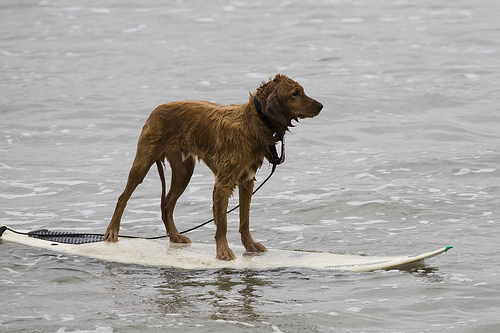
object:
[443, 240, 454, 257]
tip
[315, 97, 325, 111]
tip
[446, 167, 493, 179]
foam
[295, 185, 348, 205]
foam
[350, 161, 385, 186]
foam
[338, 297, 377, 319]
foam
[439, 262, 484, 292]
foam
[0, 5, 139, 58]
water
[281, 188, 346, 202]
foam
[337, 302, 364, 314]
foam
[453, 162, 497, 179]
foam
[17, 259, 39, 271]
foam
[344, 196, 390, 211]
foam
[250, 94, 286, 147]
dog collar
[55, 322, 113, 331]
foam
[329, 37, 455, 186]
ocean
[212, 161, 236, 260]
dog leg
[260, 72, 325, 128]
head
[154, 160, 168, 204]
tail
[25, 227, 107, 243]
black panel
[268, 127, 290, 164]
clip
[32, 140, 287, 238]
leash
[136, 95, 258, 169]
torso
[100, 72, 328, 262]
dog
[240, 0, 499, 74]
water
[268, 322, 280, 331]
foam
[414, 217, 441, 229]
foam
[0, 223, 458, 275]
board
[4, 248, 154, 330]
water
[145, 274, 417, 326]
water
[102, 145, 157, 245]
leg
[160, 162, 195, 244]
leg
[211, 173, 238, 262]
leg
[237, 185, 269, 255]
leg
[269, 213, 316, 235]
foam